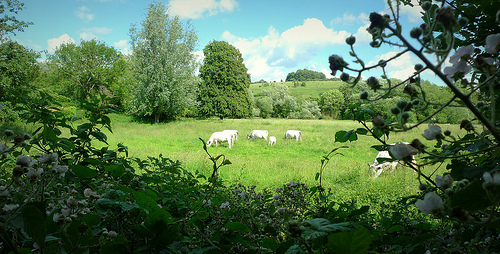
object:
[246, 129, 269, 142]
cows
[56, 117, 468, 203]
pasture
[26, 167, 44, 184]
flowers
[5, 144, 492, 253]
foreground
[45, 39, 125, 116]
trees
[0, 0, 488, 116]
background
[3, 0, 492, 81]
sky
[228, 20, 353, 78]
clouds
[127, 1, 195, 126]
tree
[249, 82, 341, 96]
meadow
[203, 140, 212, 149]
head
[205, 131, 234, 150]
cow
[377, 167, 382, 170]
ear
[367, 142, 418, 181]
cow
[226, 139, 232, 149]
legs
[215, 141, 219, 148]
leg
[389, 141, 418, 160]
flower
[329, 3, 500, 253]
plant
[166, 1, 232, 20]
cloud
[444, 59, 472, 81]
flowers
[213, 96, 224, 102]
leaves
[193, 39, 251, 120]
tree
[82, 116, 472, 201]
grass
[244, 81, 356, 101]
hills